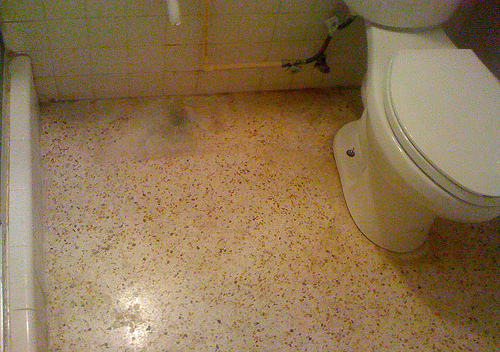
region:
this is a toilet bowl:
[314, 45, 494, 247]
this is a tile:
[84, 41, 124, 81]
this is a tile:
[114, 38, 159, 75]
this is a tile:
[208, 6, 280, 47]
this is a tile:
[35, 16, 93, 56]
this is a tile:
[122, 41, 160, 71]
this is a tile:
[120, 66, 164, 107]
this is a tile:
[244, 13, 278, 47]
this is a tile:
[11, 19, 39, 57]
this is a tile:
[194, 56, 235, 86]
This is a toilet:
[297, 2, 497, 275]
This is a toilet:
[278, 4, 497, 305]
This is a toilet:
[308, 7, 499, 287]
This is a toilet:
[303, 5, 496, 272]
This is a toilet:
[325, 8, 499, 290]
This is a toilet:
[318, 10, 499, 242]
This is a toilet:
[314, 11, 496, 326]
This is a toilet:
[313, 5, 497, 292]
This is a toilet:
[319, 2, 499, 287]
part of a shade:
[383, 205, 416, 232]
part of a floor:
[241, 207, 278, 259]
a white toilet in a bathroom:
[324, 1, 499, 249]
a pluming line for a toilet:
[198, 13, 370, 78]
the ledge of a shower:
[2, 47, 44, 349]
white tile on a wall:
[54, 76, 96, 100]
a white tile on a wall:
[87, 17, 128, 48]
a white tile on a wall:
[167, 46, 200, 71]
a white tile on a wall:
[241, 15, 275, 41]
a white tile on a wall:
[1, 21, 48, 51]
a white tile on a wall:
[56, 78, 96, 98]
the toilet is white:
[335, 1, 497, 257]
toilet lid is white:
[391, 46, 498, 193]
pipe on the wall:
[199, 16, 358, 76]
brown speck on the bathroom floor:
[216, 242, 221, 252]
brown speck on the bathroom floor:
[218, 243, 223, 256]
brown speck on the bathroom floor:
[165, 227, 173, 235]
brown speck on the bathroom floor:
[140, 215, 145, 226]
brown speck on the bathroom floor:
[138, 252, 144, 259]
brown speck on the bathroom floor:
[128, 240, 134, 246]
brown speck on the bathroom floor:
[100, 241, 106, 252]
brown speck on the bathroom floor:
[145, 318, 150, 328]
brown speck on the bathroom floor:
[208, 338, 219, 348]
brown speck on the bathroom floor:
[213, 314, 220, 323]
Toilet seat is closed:
[374, 40, 499, 207]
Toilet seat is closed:
[356, 43, 498, 226]